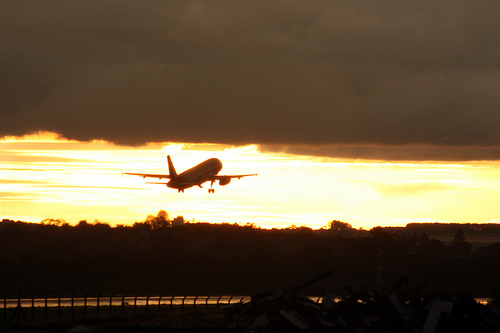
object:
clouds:
[77, 135, 94, 144]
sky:
[0, 0, 500, 210]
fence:
[0, 293, 255, 327]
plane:
[123, 155, 259, 193]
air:
[3, 0, 498, 295]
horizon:
[1, 207, 497, 240]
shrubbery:
[3, 222, 500, 295]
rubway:
[0, 295, 364, 311]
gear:
[176, 188, 186, 193]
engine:
[219, 177, 231, 187]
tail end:
[167, 154, 173, 161]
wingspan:
[122, 167, 257, 184]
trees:
[429, 236, 450, 274]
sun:
[158, 142, 189, 160]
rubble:
[356, 326, 365, 333]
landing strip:
[0, 295, 498, 316]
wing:
[212, 173, 258, 181]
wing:
[123, 172, 178, 179]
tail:
[166, 155, 179, 178]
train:
[406, 223, 499, 234]